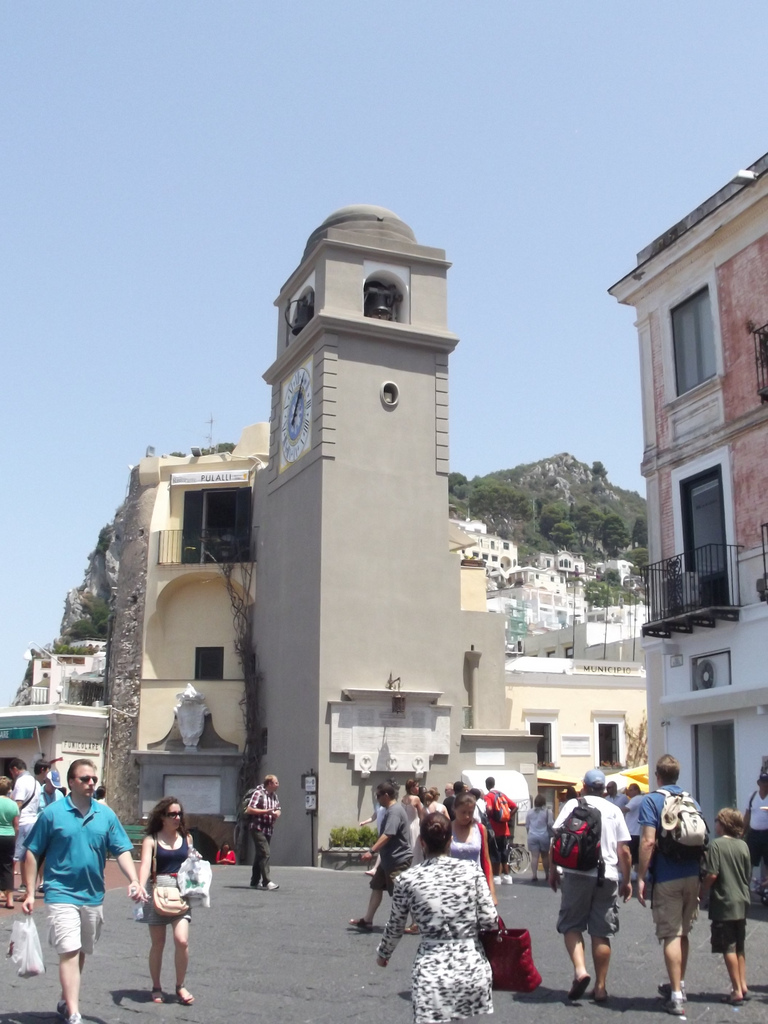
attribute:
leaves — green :
[508, 522, 537, 541]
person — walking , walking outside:
[376, 811, 542, 1021]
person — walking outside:
[134, 792, 199, 1013]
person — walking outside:
[14, 756, 141, 1022]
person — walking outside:
[550, 764, 633, 1004]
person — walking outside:
[632, 752, 713, 1021]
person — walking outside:
[699, 803, 760, 1004]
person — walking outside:
[346, 784, 415, 929]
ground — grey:
[9, 894, 767, 1022]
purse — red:
[482, 908, 544, 995]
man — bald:
[242, 769, 282, 889]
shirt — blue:
[23, 792, 132, 896]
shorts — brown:
[650, 875, 702, 937]